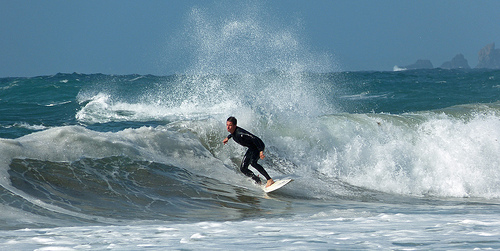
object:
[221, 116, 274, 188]
man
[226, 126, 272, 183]
suit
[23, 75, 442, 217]
water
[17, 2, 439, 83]
sky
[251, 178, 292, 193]
board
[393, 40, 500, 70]
rocks